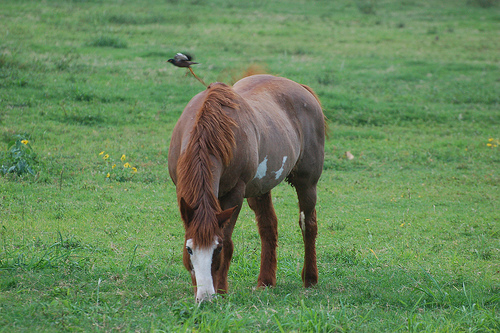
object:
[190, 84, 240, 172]
mane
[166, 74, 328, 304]
horse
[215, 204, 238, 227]
ear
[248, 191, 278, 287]
leg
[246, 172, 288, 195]
stomach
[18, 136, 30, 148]
flowers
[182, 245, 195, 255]
eyes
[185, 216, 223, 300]
face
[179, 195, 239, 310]
head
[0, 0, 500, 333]
grass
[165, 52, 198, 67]
bird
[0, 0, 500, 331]
meadow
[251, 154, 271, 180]
spots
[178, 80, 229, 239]
fur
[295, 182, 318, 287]
legs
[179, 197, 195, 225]
ears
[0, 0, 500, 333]
field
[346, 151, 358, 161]
rock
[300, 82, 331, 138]
tail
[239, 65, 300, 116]
back